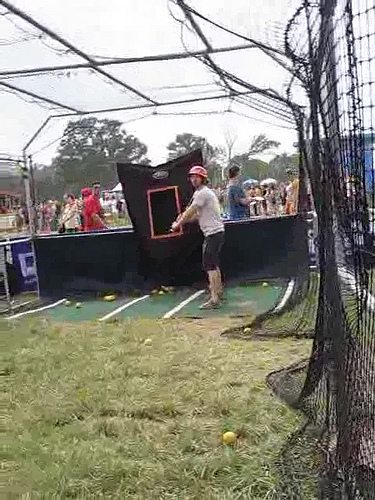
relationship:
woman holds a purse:
[52, 188, 85, 248] [49, 215, 70, 233]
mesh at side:
[185, 1, 374, 496] [291, 76, 368, 434]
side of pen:
[291, 76, 368, 434] [3, 14, 371, 494]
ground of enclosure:
[18, 290, 301, 327] [1, 0, 374, 498]